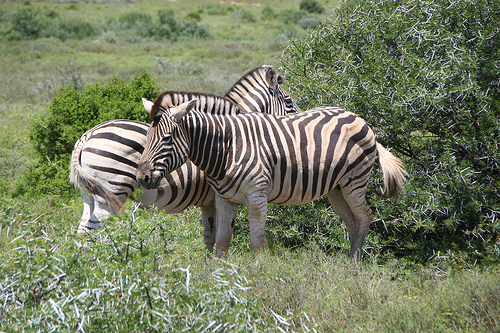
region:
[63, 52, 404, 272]
two zebras standing in the grass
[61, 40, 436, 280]
a group of zebras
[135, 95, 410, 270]
a zebra in the wild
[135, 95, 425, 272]
a zebra facing the left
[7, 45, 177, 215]
a green bush behind a zebra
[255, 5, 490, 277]
a large green bush next to zebras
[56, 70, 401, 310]
zebras grazing in a field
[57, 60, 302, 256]
a zebra facing to the right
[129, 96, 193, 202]
the head of a zebra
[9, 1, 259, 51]
small bushes in the grass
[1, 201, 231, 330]
the long grass under the zebras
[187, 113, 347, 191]
the horizontal stripes on the zebra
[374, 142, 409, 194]
the fluffy white tail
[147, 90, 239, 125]
the mohawk hair on the neck of the zebra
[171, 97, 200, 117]
the white ear of the zebra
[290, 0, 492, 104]
the bushes behind the zebras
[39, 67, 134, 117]
the bright green bush behind the zebra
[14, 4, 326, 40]
the shrubs in the field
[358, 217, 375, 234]
part fo a knee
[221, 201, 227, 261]
part f a knee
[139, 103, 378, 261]
Zebra closer to the camera facing left.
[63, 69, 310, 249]
Zebra in back facing right.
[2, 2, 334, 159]
Out of focus field in background.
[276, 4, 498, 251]
Large bushes on the right.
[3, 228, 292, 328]
Part of a bush very close to camera.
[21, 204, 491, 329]
Rough wild grass under the zebras.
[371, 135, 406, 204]
Left facing zebra's tail swaying freely.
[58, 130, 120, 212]
Right facing zebra's tail held close.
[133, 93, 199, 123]
Zebra's ears being held out stiff.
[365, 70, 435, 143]
green leaves on the tree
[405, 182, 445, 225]
green leaves on the tree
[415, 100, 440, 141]
green leaves on the tree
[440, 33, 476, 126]
green leaves on the tree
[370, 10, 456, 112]
green leaves on the tree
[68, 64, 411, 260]
two zebras facing away from each other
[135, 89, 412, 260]
zebra facing towards left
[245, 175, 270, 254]
front left leg of front zebra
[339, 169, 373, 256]
back left leg of front zebra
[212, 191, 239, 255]
front right leg of front zebra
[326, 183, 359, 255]
back right leg of front zebra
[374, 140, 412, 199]
bushy tail of front zebra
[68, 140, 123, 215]
bushy tail of back zebra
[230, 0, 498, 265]
large thorny bush near zebras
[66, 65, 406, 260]
two napping zebras in a field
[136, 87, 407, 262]
standing black and white striped zebra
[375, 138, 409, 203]
swinging zebra tail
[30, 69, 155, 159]
small green scrub bush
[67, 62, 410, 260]
two zebras standing front to back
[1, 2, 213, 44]
line of scrub bushes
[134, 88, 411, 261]
zebra with half closed eyes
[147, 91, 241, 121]
upright black and white zebra mane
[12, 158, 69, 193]
small green bush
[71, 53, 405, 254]
two zebra in the plaid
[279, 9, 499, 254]
big bush with dark green leaves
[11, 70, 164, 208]
small light green bush in the ground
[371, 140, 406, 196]
large tail of zebra in front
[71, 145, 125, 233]
large tail of zebra in the back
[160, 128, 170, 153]
small left black eye of zebra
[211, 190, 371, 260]
four legs of zebra in front